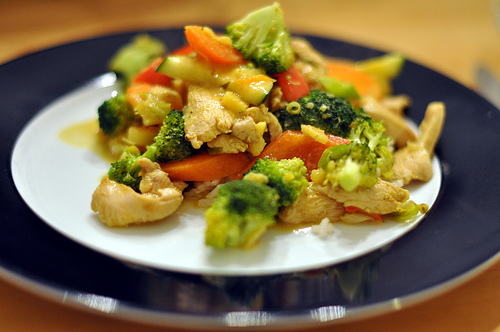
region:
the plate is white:
[2, 54, 449, 264]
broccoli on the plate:
[205, 172, 287, 259]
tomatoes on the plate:
[170, 17, 240, 73]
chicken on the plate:
[85, 158, 187, 225]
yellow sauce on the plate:
[62, 117, 124, 166]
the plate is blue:
[5, 22, 499, 322]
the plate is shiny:
[2, 7, 496, 319]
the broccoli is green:
[201, 172, 273, 247]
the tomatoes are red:
[168, 18, 240, 69]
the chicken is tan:
[80, 172, 181, 224]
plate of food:
[61, 12, 431, 269]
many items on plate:
[101, 21, 421, 243]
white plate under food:
[38, 103, 97, 200]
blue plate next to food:
[436, 196, 486, 261]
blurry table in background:
[358, 31, 473, 86]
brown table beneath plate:
[436, 283, 495, 328]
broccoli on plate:
[228, 156, 275, 233]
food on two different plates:
[37, 17, 439, 300]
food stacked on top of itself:
[133, 9, 354, 222]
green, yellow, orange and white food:
[116, 28, 389, 237]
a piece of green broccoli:
[226, 3, 302, 76]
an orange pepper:
[179, 19, 249, 71]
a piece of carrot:
[159, 144, 251, 182]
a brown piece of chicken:
[80, 154, 182, 232]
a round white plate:
[7, 78, 444, 278]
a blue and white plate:
[0, 19, 499, 330]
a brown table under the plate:
[1, 0, 498, 329]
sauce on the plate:
[57, 111, 124, 166]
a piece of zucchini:
[148, 50, 275, 108]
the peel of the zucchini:
[152, 51, 170, 75]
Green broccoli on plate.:
[211, 169, 289, 277]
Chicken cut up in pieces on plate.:
[95, 142, 192, 251]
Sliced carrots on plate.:
[176, 142, 282, 232]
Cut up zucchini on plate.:
[153, 35, 251, 157]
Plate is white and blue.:
[14, 82, 384, 293]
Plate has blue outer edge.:
[14, 17, 425, 319]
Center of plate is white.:
[40, 80, 325, 317]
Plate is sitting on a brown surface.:
[323, 244, 449, 329]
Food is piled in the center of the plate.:
[86, 33, 446, 213]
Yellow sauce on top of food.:
[73, 92, 403, 327]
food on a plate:
[124, 37, 425, 242]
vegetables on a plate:
[120, 38, 346, 238]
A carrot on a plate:
[158, 149, 262, 194]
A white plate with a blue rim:
[16, 181, 331, 322]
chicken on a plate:
[65, 145, 177, 235]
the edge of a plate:
[297, 250, 482, 318]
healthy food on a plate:
[68, 47, 417, 255]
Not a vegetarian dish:
[95, 49, 389, 259]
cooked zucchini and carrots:
[143, 16, 277, 100]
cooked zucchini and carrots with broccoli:
[162, 27, 360, 148]